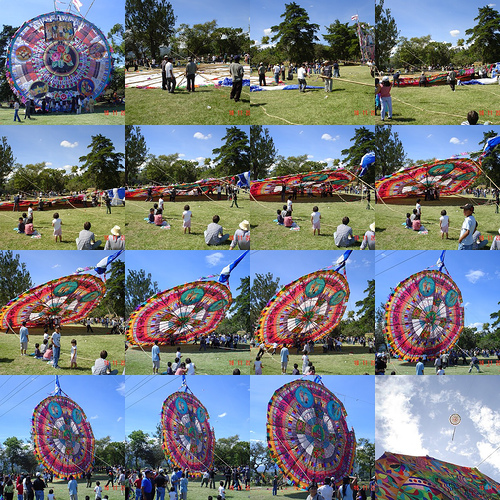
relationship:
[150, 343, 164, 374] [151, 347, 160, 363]
person wearing shirt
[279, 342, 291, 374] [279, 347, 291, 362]
person wearing shirt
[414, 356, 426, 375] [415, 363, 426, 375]
person wearing shirt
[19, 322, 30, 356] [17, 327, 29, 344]
person wearing shirt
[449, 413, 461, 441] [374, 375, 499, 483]
kite in sky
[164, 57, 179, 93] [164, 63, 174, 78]
person wearing shirt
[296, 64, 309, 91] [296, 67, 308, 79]
person wearing shirt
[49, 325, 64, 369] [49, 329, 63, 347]
person wearing shirt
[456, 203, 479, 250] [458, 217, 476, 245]
person wearing shirt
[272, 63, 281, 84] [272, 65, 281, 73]
person wearing shirt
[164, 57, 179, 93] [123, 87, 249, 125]
person on grass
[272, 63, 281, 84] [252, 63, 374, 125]
person on grass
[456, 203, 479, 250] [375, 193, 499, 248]
person on grass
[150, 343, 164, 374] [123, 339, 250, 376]
person on grass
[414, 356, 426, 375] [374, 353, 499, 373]
person on grass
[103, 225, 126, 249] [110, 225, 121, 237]
person wearing hat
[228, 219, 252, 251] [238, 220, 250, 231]
person wearing hat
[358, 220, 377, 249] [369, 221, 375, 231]
person wearing hat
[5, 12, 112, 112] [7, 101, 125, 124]
kite on ground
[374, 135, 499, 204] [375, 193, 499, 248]
kite on ground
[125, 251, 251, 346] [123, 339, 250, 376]
kite on ground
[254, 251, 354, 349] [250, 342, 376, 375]
kite on ground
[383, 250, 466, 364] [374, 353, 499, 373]
kite on ground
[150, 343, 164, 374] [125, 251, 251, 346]
person next to kite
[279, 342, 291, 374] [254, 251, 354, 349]
person next to kite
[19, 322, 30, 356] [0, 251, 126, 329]
person next to kite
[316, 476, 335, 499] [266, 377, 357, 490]
person next to kite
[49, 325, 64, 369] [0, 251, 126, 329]
person next to kite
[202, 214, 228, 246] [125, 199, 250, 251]
person on grass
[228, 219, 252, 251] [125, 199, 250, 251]
person on grass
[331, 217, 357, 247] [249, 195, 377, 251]
person on grass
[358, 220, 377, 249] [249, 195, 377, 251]
person on grass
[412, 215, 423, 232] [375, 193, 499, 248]
person on grass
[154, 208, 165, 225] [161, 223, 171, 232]
person on mat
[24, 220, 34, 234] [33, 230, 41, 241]
person on mat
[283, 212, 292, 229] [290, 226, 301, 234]
person on mat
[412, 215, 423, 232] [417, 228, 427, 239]
person on mat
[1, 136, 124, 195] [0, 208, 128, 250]
trees near grass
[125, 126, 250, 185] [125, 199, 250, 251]
trees near grass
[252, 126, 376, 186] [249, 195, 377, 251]
trees near grass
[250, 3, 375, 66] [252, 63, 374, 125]
trees near grass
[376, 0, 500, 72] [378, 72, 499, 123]
trees near grass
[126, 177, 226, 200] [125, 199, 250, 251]
kite on grass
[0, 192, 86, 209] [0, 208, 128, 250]
kite on grass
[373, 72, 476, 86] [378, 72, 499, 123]
kite on grass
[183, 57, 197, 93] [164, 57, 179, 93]
person next to person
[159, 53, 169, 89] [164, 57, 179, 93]
person next to person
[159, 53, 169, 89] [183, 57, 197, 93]
person talking to person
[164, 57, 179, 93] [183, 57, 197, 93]
person talking to person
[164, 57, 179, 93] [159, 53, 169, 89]
person talking to person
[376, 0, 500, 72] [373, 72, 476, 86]
trees behind kite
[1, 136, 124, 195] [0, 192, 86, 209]
trees behind kite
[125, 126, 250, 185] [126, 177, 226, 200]
trees behind kite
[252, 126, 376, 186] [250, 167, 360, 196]
trees behind kite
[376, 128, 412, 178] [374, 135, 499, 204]
trees behind kite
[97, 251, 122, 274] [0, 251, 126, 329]
balloon attached to kite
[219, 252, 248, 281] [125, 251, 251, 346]
balloon attached to kite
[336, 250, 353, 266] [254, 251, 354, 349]
balloon attached to kite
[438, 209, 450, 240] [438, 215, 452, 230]
kid wearing shirt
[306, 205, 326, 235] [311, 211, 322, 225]
kid wearing shirt